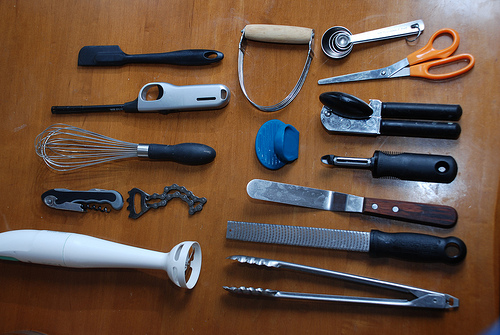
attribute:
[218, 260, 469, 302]
tong — metal, silver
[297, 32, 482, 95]
scissor — orange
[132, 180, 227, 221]
bottle opener — black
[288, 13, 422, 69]
spoon — metal, measuring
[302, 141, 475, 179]
peeler — black, round, vegetable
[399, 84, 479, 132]
handle — black, wooden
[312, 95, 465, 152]
opener — can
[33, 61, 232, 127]
lighter — large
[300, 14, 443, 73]
utensil — small, white, kitchen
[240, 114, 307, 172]
spatual — plastic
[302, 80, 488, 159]
can opener — table, hand held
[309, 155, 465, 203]
knife — peeling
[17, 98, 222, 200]
mixer — hand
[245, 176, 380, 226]
blade — silver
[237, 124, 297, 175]
smoother — frosting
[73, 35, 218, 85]
cork — folding